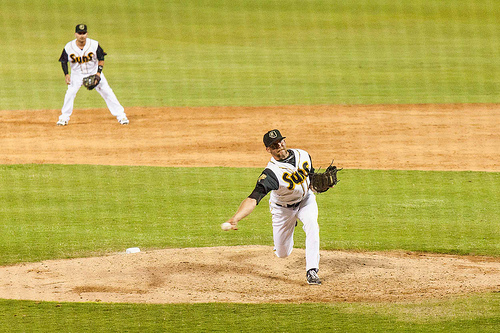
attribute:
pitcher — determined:
[214, 123, 363, 293]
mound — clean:
[51, 239, 446, 304]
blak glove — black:
[308, 162, 340, 191]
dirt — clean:
[0, 110, 497, 132]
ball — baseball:
[216, 218, 234, 234]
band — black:
[95, 63, 105, 74]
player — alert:
[54, 22, 130, 126]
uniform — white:
[249, 147, 319, 271]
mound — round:
[2, 238, 499, 314]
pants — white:
[55, 72, 132, 122]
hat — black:
[258, 126, 305, 148]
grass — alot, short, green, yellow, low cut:
[3, 5, 498, 102]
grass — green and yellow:
[153, 0, 495, 120]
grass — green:
[0, 0, 495, 113]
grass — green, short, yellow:
[7, 3, 499, 331]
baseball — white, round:
[219, 214, 238, 230]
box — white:
[91, 205, 196, 302]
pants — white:
[271, 191, 323, 271]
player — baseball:
[223, 123, 353, 292]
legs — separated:
[60, 79, 133, 133]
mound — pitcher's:
[4, 232, 498, 318]